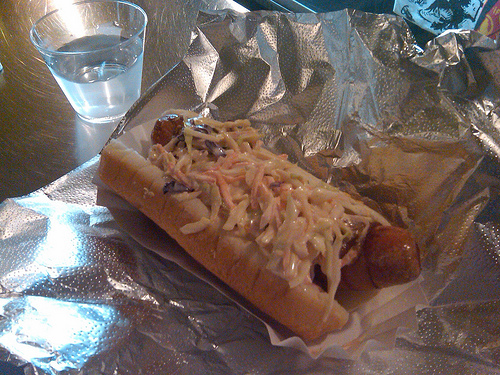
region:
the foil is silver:
[50, 258, 190, 367]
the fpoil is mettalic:
[57, 270, 189, 371]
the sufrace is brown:
[17, 95, 67, 163]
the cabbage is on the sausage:
[179, 138, 350, 267]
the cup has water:
[39, 49, 147, 121]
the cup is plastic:
[42, 45, 140, 120]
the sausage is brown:
[355, 224, 427, 282]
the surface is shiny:
[12, 88, 70, 161]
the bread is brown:
[111, 145, 333, 330]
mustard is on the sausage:
[115, 104, 430, 294]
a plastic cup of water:
[29, 0, 148, 123]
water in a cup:
[48, 34, 142, 120]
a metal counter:
[1, 0, 249, 200]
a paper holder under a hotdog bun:
[93, 112, 434, 366]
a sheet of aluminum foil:
[0, 8, 496, 373]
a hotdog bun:
[101, 108, 391, 338]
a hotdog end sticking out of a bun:
[322, 225, 417, 290]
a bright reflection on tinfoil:
[10, 295, 105, 366]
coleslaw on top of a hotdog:
[145, 117, 385, 308]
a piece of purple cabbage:
[158, 179, 192, 195]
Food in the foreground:
[91, 100, 436, 345]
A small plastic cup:
[25, 5, 160, 131]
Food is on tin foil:
[3, 3, 498, 374]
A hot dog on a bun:
[106, 103, 442, 354]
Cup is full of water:
[21, 5, 160, 130]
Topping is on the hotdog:
[161, 116, 368, 288]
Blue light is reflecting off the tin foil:
[2, 197, 127, 367]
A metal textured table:
[3, 0, 228, 200]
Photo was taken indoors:
[3, 3, 498, 364]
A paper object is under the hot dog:
[81, 100, 448, 364]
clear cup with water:
[29, 1, 147, 123]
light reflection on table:
[49, 1, 85, 37]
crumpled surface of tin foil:
[3, 10, 496, 373]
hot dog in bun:
[103, 114, 423, 337]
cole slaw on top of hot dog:
[153, 125, 355, 277]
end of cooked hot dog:
[371, 219, 422, 291]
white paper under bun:
[95, 115, 433, 359]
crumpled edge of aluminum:
[349, 9, 499, 66]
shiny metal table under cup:
[1, 0, 238, 197]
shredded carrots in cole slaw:
[200, 154, 296, 235]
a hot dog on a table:
[85, 140, 402, 335]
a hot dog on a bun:
[65, 50, 441, 317]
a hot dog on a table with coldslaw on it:
[110, 120, 495, 335]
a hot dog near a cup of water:
[105, 55, 476, 320]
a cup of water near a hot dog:
[22, 21, 194, 162]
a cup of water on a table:
[45, 0, 191, 132]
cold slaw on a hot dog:
[143, 88, 393, 280]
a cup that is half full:
[36, 0, 204, 131]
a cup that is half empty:
[36, 0, 208, 148]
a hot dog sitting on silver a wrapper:
[74, 83, 439, 362]